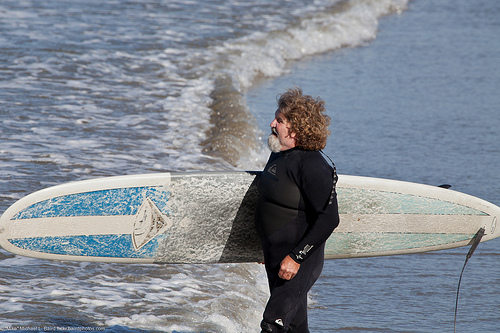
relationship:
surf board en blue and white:
[4, 164, 498, 271] [4, 171, 176, 269]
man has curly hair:
[243, 77, 345, 333] [275, 80, 338, 154]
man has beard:
[243, 77, 345, 333] [263, 133, 285, 157]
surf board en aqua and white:
[4, 164, 498, 271] [4, 171, 176, 269]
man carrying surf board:
[243, 77, 345, 333] [4, 164, 498, 271]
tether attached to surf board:
[444, 216, 495, 329] [4, 164, 498, 271]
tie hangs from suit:
[322, 163, 343, 210] [244, 145, 349, 333]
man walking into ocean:
[243, 77, 345, 333] [3, 1, 247, 326]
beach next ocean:
[320, 6, 500, 331] [3, 1, 247, 326]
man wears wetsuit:
[243, 77, 345, 333] [244, 145, 349, 333]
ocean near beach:
[3, 1, 247, 326] [320, 6, 500, 331]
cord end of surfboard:
[444, 216, 495, 329] [4, 164, 498, 271]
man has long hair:
[243, 77, 345, 333] [275, 80, 338, 154]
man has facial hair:
[243, 77, 345, 333] [263, 133, 285, 157]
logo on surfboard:
[126, 193, 176, 254] [4, 164, 498, 271]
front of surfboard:
[4, 171, 176, 269] [4, 164, 498, 271]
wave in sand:
[152, 0, 409, 170] [320, 6, 500, 331]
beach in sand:
[244, 0, 500, 333] [320, 6, 500, 331]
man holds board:
[243, 77, 345, 333] [4, 164, 498, 271]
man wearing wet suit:
[243, 77, 345, 333] [244, 145, 349, 333]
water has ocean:
[3, 1, 247, 326] [0, 0, 409, 333]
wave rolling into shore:
[152, 1, 272, 170] [320, 6, 500, 331]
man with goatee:
[243, 77, 345, 333] [263, 133, 285, 157]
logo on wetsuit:
[265, 160, 281, 179] [244, 145, 349, 333]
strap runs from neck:
[315, 145, 343, 206] [269, 145, 319, 155]